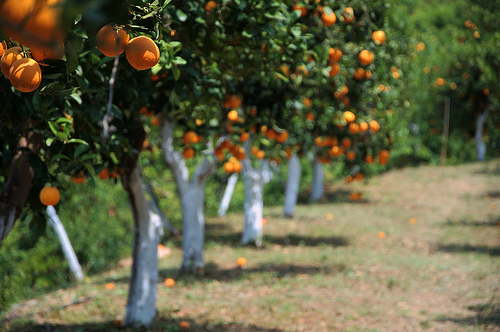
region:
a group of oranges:
[14, 9, 194, 159]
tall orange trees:
[5, 10, 235, 310]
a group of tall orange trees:
[16, 11, 399, 317]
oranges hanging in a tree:
[19, 13, 413, 170]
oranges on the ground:
[71, 188, 401, 315]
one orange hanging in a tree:
[31, 177, 76, 223]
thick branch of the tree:
[99, 154, 204, 329]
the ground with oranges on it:
[76, 170, 414, 322]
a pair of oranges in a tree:
[89, 14, 176, 76]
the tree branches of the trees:
[36, 102, 387, 313]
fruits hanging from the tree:
[103, 31, 168, 77]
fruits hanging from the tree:
[285, 70, 390, 161]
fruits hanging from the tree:
[318, 32, 400, 94]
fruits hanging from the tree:
[352, 61, 396, 162]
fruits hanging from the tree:
[221, 141, 276, 190]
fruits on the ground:
[147, 255, 202, 318]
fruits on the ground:
[203, 230, 280, 292]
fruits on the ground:
[295, 168, 402, 263]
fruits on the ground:
[375, 213, 427, 238]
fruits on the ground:
[178, 208, 284, 303]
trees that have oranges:
[9, 13, 486, 330]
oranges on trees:
[37, 25, 492, 212]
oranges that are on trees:
[7, 8, 449, 205]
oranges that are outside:
[29, 7, 474, 232]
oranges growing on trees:
[29, 7, 480, 189]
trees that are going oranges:
[29, 8, 444, 251]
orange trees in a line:
[22, 26, 460, 330]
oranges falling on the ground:
[104, 194, 392, 324]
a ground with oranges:
[79, 180, 433, 330]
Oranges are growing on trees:
[72, 28, 407, 259]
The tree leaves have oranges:
[80, 150, 285, 330]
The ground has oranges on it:
[182, 193, 437, 314]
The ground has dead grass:
[235, 195, 474, 325]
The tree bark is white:
[97, 194, 254, 317]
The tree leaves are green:
[72, 98, 168, 174]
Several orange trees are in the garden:
[234, 24, 496, 192]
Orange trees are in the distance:
[375, 0, 492, 147]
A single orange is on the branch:
[25, 180, 107, 230]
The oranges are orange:
[39, 85, 220, 272]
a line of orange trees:
[7, 13, 419, 326]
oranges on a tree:
[97, 28, 154, 75]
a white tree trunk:
[127, 178, 167, 318]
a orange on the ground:
[157, 273, 178, 294]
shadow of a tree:
[125, 253, 339, 303]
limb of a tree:
[6, 131, 41, 212]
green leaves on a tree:
[41, 81, 90, 146]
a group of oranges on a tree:
[305, 101, 387, 163]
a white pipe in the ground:
[49, 208, 103, 284]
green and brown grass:
[251, 247, 395, 314]